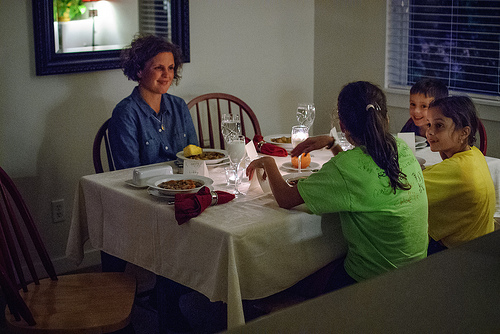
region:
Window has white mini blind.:
[376, 0, 498, 105]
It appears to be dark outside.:
[376, 1, 499, 106]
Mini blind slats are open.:
[381, 3, 497, 113]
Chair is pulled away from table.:
[2, 169, 133, 330]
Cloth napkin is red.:
[169, 182, 242, 232]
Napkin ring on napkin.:
[203, 182, 226, 214]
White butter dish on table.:
[119, 152, 182, 193]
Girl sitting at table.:
[81, 26, 216, 188]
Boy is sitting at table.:
[396, 72, 458, 171]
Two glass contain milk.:
[225, 126, 316, 185]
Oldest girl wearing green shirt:
[245, 79, 430, 281]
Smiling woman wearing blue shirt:
[105, 34, 201, 169]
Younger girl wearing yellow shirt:
[420, 94, 495, 248]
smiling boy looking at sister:
[406, 79, 451, 144]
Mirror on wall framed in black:
[32, 1, 193, 76]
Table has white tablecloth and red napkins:
[62, 128, 499, 330]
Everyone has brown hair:
[120, 31, 479, 193]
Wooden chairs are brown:
[0, 91, 487, 331]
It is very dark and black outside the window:
[388, 0, 499, 102]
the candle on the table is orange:
[289, 146, 310, 168]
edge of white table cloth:
[209, 235, 274, 302]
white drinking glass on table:
[282, 97, 321, 138]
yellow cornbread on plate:
[177, 143, 207, 164]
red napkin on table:
[163, 190, 243, 220]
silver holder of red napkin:
[205, 185, 220, 206]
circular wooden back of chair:
[189, 89, 272, 144]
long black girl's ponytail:
[354, 96, 417, 189]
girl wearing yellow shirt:
[426, 147, 493, 243]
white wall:
[18, 86, 101, 152]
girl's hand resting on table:
[239, 158, 301, 218]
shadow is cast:
[48, 77, 117, 149]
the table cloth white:
[226, 207, 268, 255]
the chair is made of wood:
[11, 52, 471, 332]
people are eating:
[23, 15, 498, 315]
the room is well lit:
[12, 9, 450, 294]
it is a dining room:
[16, 15, 499, 325]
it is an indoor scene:
[12, 25, 496, 285]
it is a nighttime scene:
[8, 14, 488, 312]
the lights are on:
[9, 16, 496, 300]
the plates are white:
[154, 125, 354, 222]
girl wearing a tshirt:
[245, 83, 427, 283]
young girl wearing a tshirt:
[410, 90, 495, 250]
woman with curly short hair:
[105, 35, 200, 170]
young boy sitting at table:
[392, 75, 447, 140]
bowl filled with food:
[147, 172, 212, 192]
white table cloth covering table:
[60, 130, 492, 322]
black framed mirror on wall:
[32, 0, 189, 80]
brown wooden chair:
[0, 171, 140, 327]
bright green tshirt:
[297, 135, 427, 275]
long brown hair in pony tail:
[335, 76, 410, 196]